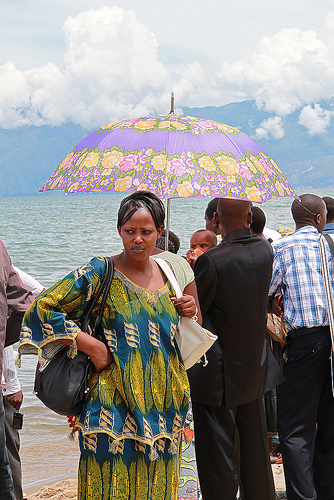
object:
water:
[3, 194, 332, 499]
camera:
[10, 412, 24, 430]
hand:
[7, 387, 23, 411]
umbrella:
[37, 92, 299, 202]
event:
[5, 76, 330, 496]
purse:
[153, 257, 218, 372]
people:
[0, 239, 24, 497]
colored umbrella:
[35, 91, 296, 214]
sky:
[1, 1, 330, 188]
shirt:
[268, 225, 332, 327]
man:
[269, 195, 333, 498]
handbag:
[33, 255, 114, 416]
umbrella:
[35, 111, 302, 203]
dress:
[23, 256, 189, 496]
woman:
[17, 187, 209, 496]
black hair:
[117, 190, 165, 228]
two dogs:
[213, 27, 323, 109]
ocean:
[1, 188, 332, 289]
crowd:
[0, 189, 331, 496]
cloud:
[252, 113, 286, 145]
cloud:
[295, 101, 331, 142]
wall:
[106, 56, 161, 106]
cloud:
[0, 70, 44, 125]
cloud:
[30, 59, 65, 130]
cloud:
[108, 14, 331, 98]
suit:
[189, 225, 271, 495]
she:
[14, 189, 197, 499]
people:
[198, 187, 273, 500]